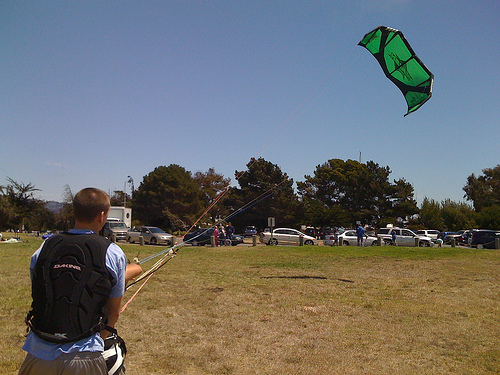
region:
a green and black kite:
[354, 23, 436, 117]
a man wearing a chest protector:
[21, 232, 112, 342]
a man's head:
[72, 186, 109, 233]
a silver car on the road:
[323, 226, 383, 242]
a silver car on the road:
[257, 225, 313, 245]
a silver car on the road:
[127, 226, 173, 244]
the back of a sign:
[267, 215, 275, 228]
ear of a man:
[98, 209, 105, 222]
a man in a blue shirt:
[355, 222, 367, 247]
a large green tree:
[129, 165, 209, 239]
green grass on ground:
[199, 247, 217, 264]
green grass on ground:
[249, 251, 264, 265]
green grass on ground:
[284, 246, 306, 265]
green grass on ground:
[328, 250, 336, 261]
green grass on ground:
[349, 257, 368, 264]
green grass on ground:
[368, 241, 390, 257]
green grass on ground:
[398, 246, 415, 261]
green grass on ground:
[425, 246, 439, 269]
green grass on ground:
[441, 244, 460, 263]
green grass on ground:
[194, 245, 204, 266]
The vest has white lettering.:
[51, 259, 81, 271]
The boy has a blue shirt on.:
[22, 227, 122, 361]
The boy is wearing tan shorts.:
[18, 350, 109, 374]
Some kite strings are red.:
[179, 174, 233, 214]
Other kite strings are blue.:
[229, 185, 286, 222]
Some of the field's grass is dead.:
[169, 313, 321, 374]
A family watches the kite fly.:
[206, 220, 238, 247]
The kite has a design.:
[384, 51, 419, 81]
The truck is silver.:
[372, 225, 432, 247]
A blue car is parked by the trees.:
[242, 222, 257, 237]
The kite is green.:
[356, 25, 435, 117]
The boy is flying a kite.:
[20, 24, 436, 374]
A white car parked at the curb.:
[261, 226, 316, 246]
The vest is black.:
[29, 230, 116, 347]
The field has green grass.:
[183, 245, 498, 373]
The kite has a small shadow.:
[262, 274, 354, 285]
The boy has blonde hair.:
[70, 186, 107, 226]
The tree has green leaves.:
[129, 165, 206, 224]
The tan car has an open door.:
[124, 225, 175, 245]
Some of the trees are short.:
[418, 196, 476, 229]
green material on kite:
[394, 45, 404, 58]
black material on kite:
[386, 69, 393, 80]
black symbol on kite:
[390, 53, 412, 79]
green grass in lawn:
[303, 247, 322, 263]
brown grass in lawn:
[258, 324, 281, 344]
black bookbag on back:
[53, 279, 71, 301]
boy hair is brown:
[80, 197, 94, 211]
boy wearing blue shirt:
[111, 253, 121, 267]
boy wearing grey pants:
[82, 360, 94, 368]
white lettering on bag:
[49, 262, 86, 272]